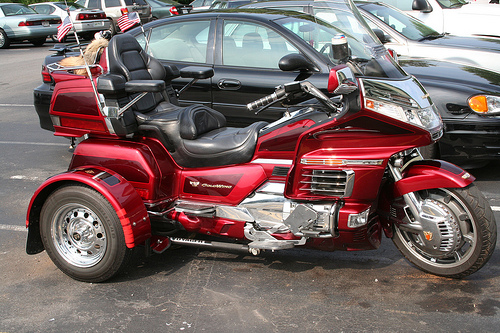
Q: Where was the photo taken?
A: In a parking lot.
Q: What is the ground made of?
A: Asphalt.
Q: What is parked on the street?
A: The red bike is.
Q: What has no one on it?
A: The red bike.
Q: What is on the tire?
A: A silver rim is.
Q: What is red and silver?
A: The body of the bike.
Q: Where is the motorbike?
A: Parked next to a black car.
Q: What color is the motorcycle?
A: Red.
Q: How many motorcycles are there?
A: One.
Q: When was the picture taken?
A: Daytime.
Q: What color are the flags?
A: Red, white, and blue.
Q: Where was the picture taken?
A: Outdoor in a parking lot.